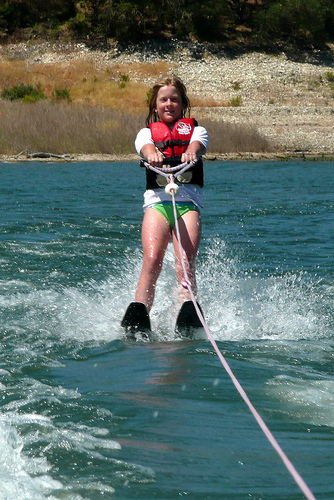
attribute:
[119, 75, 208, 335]
skier — smiling, female, water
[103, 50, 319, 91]
hillside — rocking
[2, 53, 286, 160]
grass — green, brown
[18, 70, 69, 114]
bushes — green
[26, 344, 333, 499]
blue water — clear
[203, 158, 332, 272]
blue water — clear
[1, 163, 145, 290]
blue water — clear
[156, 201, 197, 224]
bikini — green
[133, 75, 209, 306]
girl — young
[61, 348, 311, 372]
waves — splashing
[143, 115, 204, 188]
vest — red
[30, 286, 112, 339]
waves — white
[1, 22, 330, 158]
hill — grassy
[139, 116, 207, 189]
vest — red, safety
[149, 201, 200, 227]
swimming trunks — green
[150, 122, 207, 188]
vest — red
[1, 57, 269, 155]
grass — dried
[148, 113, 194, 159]
lifejacket — red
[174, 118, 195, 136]
symbol — white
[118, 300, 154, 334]
ski — water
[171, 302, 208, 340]
ski — water